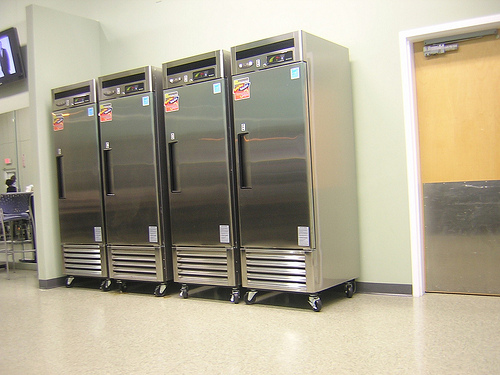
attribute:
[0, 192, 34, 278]
chair — blue, printed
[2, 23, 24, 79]
tv — hanging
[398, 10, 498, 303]
door frame — white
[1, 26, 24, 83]
tv — on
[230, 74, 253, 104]
picture — red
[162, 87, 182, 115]
picture — red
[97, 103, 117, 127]
picture — red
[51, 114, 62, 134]
picture — red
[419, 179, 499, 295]
bottom — silver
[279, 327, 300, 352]
light — reflecting